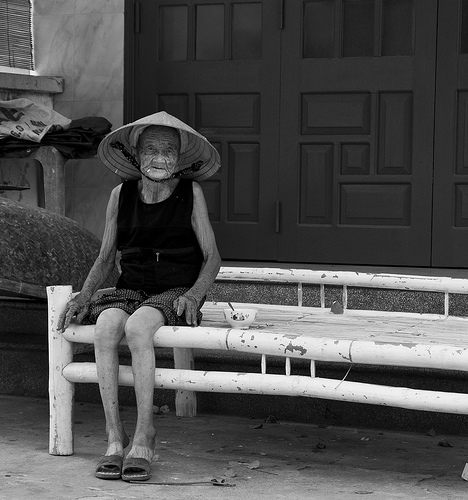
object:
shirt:
[114, 177, 204, 295]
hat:
[97, 109, 222, 183]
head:
[135, 126, 181, 179]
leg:
[92, 307, 124, 433]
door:
[122, 0, 468, 270]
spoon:
[228, 302, 235, 312]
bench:
[46, 266, 466, 455]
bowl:
[222, 308, 258, 331]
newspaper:
[0, 98, 73, 144]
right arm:
[55, 189, 118, 332]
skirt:
[80, 286, 208, 326]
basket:
[0, 195, 123, 298]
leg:
[123, 306, 166, 428]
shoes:
[94, 453, 123, 480]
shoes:
[121, 456, 151, 482]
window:
[0, 0, 33, 76]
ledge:
[0, 72, 64, 94]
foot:
[126, 436, 156, 469]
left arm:
[184, 195, 222, 309]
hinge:
[275, 202, 280, 235]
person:
[55, 124, 222, 470]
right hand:
[55, 291, 90, 334]